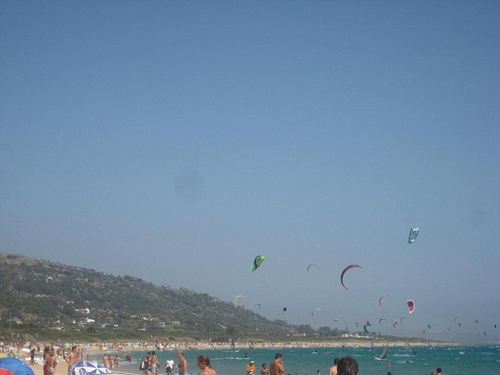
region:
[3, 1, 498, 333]
blue of daytime sky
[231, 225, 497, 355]
parasails in the air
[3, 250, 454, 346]
trees and buildings on hill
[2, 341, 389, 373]
crowd of people on beach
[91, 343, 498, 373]
surface of ocean water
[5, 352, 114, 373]
tops of beach umbrellas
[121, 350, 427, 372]
people swimming in water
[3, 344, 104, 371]
surface of sandy beach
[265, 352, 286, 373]
back of shirtless man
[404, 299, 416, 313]
underside of flying parasail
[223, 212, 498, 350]
kites in the sky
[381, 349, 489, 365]
water in an ocean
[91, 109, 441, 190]
blue sky in the distance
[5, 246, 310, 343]
grassy hill by the beach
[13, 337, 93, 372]
people at a beach area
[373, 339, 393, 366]
sail in the water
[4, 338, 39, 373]
umbrella in the sand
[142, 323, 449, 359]
shore line at the beach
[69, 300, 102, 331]
houses on the hills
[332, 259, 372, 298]
moon shaped kite in sky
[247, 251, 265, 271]
A green kite in the air.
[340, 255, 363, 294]
A red crescent moon shaped kite in the air.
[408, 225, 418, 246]
A silver, rectangle kite in the air.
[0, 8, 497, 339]
A very large area of blue sky.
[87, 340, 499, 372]
An area of blue-green sea water.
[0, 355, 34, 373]
A blue umbrella set up on the beach.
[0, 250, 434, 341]
An area of land that slopes down to meet the waters edge.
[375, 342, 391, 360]
What appears to be a sail boarder on the water.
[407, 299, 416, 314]
A red and white kite in the sky.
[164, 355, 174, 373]
A person wearing a white shirt.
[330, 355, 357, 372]
Person has dark hair.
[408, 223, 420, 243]
White and blue highest kite.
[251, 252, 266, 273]
Green and blue kite that is most visible.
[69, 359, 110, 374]
Top of a blue and white umbrella.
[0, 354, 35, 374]
A solid blue umbrella.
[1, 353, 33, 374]
Umbrella top that is solid blue.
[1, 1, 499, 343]
Blue sky with kites in it.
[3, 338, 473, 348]
Strip of sandy beach with many people between the land and water.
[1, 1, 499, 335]
A dark blue sky.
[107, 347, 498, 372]
Green body of water.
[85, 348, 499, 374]
Greenish colored water people are in.